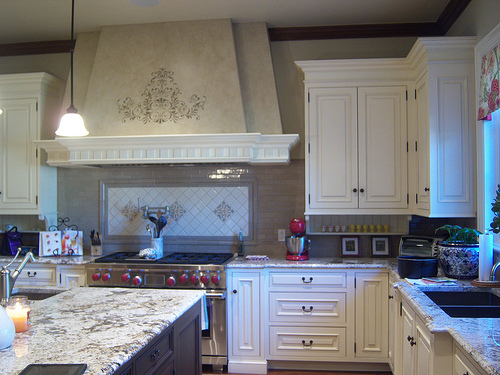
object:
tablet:
[15, 362, 87, 374]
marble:
[445, 318, 498, 373]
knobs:
[211, 274, 220, 284]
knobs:
[200, 273, 208, 283]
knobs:
[179, 274, 188, 284]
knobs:
[190, 274, 199, 284]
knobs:
[167, 274, 176, 286]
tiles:
[99, 177, 257, 246]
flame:
[14, 298, 22, 310]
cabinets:
[292, 35, 476, 219]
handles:
[302, 277, 313, 283]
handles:
[301, 338, 312, 346]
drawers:
[269, 272, 346, 288]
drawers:
[269, 293, 345, 323]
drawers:
[269, 326, 346, 357]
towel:
[200, 292, 209, 330]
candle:
[5, 298, 30, 333]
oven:
[85, 251, 237, 371]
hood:
[31, 22, 300, 168]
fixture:
[145, 216, 166, 261]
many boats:
[370, 236, 392, 257]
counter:
[388, 268, 499, 375]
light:
[429, 109, 500, 282]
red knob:
[132, 275, 142, 285]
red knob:
[121, 273, 130, 282]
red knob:
[102, 272, 111, 281]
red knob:
[92, 272, 100, 281]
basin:
[422, 291, 499, 319]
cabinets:
[224, 257, 389, 375]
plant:
[435, 225, 484, 244]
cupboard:
[227, 269, 264, 365]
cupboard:
[354, 272, 389, 362]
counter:
[0, 287, 205, 375]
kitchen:
[0, 0, 500, 374]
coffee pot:
[285, 218, 308, 260]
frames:
[340, 236, 361, 256]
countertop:
[226, 257, 386, 269]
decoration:
[116, 68, 207, 125]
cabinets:
[2, 0, 498, 375]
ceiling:
[1, 0, 471, 45]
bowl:
[285, 234, 311, 254]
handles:
[302, 306, 313, 313]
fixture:
[55, 0, 90, 137]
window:
[485, 109, 500, 252]